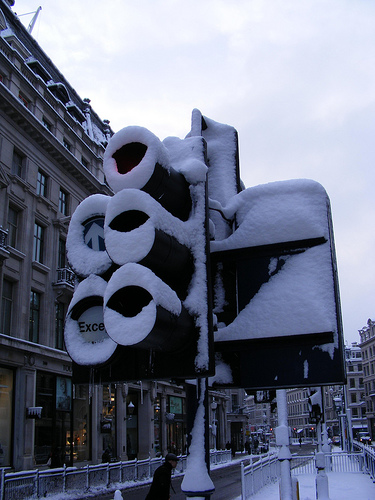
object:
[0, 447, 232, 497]
fence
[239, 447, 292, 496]
fence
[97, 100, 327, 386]
light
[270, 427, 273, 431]
lights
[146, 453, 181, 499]
man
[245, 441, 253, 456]
man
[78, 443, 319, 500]
street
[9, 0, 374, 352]
clouds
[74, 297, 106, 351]
sign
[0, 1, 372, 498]
buildings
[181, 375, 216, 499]
pole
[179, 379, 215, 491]
snow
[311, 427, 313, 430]
light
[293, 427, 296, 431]
light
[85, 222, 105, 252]
arrow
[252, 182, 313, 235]
snow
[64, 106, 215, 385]
signal light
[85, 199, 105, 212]
snow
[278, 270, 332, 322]
snow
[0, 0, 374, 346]
blue sky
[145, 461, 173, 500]
coat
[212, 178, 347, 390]
sign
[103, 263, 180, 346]
snow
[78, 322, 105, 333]
exce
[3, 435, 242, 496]
sidewalk